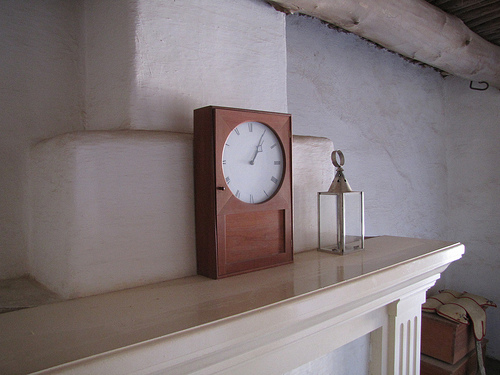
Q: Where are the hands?
A: On the clock.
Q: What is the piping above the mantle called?
A: Chimney.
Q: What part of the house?
A: Walls.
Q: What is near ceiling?
A: Log.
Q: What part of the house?
A: Chimney.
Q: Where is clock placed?
A: On mantle.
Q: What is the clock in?
A: Brown frame.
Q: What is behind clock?
A: White wall.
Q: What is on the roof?
A: Log.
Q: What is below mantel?
A: Fireplace.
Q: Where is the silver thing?
A: On the side of a clock.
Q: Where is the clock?
A: On side counter.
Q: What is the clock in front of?
A: A wall in the building.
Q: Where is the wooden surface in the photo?
A: Mantle.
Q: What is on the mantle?
A: Small wooden clock.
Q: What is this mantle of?
A: Fireplace.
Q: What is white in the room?
A: Concrete wall.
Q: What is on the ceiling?
A: Log overhead.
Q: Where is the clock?
A: On the mantle.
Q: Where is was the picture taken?
A: In a home.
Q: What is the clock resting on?
A: The fireplace mantle.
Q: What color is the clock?
A: Brown.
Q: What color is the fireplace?
A: White.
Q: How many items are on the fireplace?
A: Two.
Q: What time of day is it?
A: Daytime.